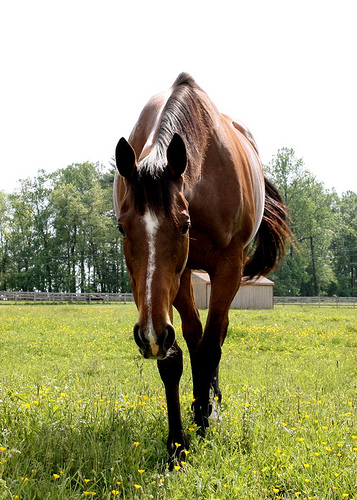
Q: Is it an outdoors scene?
A: Yes, it is outdoors.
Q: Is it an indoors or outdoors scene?
A: It is outdoors.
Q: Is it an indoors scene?
A: No, it is outdoors.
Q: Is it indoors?
A: No, it is outdoors.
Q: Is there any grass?
A: Yes, there is grass.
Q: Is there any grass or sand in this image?
A: Yes, there is grass.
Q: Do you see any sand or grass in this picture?
A: Yes, there is grass.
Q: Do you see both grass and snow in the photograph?
A: No, there is grass but no snow.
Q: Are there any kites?
A: No, there are no kites.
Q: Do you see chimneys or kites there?
A: No, there are no kites or chimneys.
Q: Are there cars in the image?
A: No, there are no cars.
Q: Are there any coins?
A: No, there are no coins.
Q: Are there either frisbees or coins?
A: No, there are no coins or frisbees.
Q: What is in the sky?
A: The clouds are in the sky.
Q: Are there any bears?
A: No, there are no bears.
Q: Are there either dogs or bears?
A: No, there are no bears or dogs.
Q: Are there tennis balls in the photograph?
A: No, there are no tennis balls.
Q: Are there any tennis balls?
A: No, there are no tennis balls.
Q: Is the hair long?
A: Yes, the hair is long.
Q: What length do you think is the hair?
A: The hair is long.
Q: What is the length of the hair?
A: The hair is long.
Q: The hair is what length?
A: The hair is long.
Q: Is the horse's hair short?
A: No, the hair is long.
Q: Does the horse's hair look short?
A: No, the hair is long.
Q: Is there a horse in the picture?
A: Yes, there is a horse.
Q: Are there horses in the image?
A: Yes, there is a horse.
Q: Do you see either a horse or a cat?
A: Yes, there is a horse.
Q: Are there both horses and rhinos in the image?
A: No, there is a horse but no rhinos.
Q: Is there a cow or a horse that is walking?
A: Yes, the horse is walking.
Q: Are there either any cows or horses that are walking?
A: Yes, the horse is walking.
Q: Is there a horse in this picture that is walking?
A: Yes, there is a horse that is walking.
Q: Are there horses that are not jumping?
A: Yes, there is a horse that is walking.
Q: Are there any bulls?
A: No, there are no bulls.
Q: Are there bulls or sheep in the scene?
A: No, there are no bulls or sheep.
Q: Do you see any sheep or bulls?
A: No, there are no bulls or sheep.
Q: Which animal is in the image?
A: The animal is a horse.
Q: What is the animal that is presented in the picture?
A: The animal is a horse.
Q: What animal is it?
A: The animal is a horse.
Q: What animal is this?
A: That is a horse.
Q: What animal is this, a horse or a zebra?
A: That is a horse.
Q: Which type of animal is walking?
A: The animal is a horse.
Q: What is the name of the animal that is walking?
A: The animal is a horse.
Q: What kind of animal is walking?
A: The animal is a horse.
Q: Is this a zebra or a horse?
A: This is a horse.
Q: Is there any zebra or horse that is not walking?
A: No, there is a horse but it is walking.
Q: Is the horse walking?
A: Yes, the horse is walking.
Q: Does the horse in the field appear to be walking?
A: Yes, the horse is walking.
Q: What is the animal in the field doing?
A: The horse is walking.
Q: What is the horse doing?
A: The horse is walking.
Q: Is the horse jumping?
A: No, the horse is walking.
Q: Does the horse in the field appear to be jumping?
A: No, the horse is walking.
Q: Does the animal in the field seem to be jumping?
A: No, the horse is walking.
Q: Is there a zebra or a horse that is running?
A: No, there is a horse but it is walking.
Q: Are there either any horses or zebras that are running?
A: No, there is a horse but it is walking.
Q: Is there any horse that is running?
A: No, there is a horse but it is walking.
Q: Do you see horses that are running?
A: No, there is a horse but it is walking.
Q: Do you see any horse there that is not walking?
A: No, there is a horse but it is walking.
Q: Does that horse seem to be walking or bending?
A: The horse is walking.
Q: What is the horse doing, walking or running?
A: The horse is walking.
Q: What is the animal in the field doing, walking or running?
A: The horse is walking.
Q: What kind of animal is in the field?
A: The animal is a horse.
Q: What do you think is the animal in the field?
A: The animal is a horse.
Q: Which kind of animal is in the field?
A: The animal is a horse.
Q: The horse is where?
A: The horse is in the field.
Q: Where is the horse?
A: The horse is in the field.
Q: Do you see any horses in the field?
A: Yes, there is a horse in the field.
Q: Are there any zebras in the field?
A: No, there is a horse in the field.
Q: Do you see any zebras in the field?
A: No, there is a horse in the field.